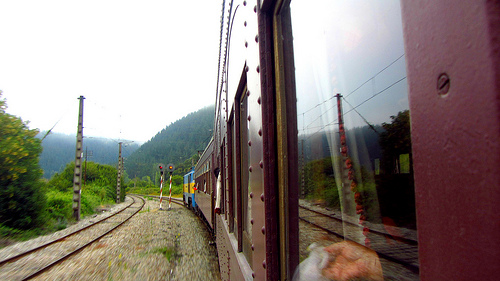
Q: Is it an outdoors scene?
A: Yes, it is outdoors.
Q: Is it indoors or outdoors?
A: It is outdoors.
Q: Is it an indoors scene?
A: No, it is outdoors.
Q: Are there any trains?
A: Yes, there is a train.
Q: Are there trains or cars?
A: Yes, there is a train.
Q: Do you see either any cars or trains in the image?
A: Yes, there is a train.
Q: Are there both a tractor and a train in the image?
A: No, there is a train but no tractors.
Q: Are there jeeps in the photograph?
A: No, there are no jeeps.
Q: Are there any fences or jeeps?
A: No, there are no jeeps or fences.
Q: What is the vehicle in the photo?
A: The vehicle is a train.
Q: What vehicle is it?
A: The vehicle is a train.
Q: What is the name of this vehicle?
A: This is a train.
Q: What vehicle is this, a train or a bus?
A: This is a train.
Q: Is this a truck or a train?
A: This is a train.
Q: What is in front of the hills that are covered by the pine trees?
A: The train is in front of the hills.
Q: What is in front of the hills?
A: The train is in front of the hills.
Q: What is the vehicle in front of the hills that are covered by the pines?
A: The vehicle is a train.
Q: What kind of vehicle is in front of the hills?
A: The vehicle is a train.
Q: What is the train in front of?
A: The train is in front of the hills.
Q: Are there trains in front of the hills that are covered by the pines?
A: Yes, there is a train in front of the hills.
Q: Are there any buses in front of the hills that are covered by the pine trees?
A: No, there is a train in front of the hills.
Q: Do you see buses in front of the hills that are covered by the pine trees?
A: No, there is a train in front of the hills.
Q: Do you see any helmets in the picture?
A: No, there are no helmets.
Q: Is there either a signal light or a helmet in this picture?
A: No, there are no helmets or traffic lights.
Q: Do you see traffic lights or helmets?
A: No, there are no helmets or traffic lights.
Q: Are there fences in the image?
A: No, there are no fences.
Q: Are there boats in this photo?
A: No, there are no boats.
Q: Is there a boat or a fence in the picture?
A: No, there are no boats or fences.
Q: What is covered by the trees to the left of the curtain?
A: The hills are covered by the pine trees.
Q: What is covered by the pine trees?
A: The hills are covered by the pine trees.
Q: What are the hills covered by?
A: The hills are covered by the pines.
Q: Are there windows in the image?
A: Yes, there is a window.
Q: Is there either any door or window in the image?
A: Yes, there is a window.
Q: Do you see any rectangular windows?
A: Yes, there is a rectangular window.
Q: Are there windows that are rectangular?
A: Yes, there is a window that is rectangular.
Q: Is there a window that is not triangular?
A: Yes, there is a rectangular window.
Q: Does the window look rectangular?
A: Yes, the window is rectangular.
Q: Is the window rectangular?
A: Yes, the window is rectangular.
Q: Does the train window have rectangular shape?
A: Yes, the window is rectangular.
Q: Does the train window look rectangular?
A: Yes, the window is rectangular.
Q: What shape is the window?
A: The window is rectangular.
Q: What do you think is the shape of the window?
A: The window is rectangular.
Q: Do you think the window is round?
A: No, the window is rectangular.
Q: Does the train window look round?
A: No, the window is rectangular.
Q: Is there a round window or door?
A: No, there is a window but it is rectangular.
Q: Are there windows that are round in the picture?
A: No, there is a window but it is rectangular.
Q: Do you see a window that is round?
A: No, there is a window but it is rectangular.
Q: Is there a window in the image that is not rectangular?
A: No, there is a window but it is rectangular.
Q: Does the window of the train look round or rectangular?
A: The window is rectangular.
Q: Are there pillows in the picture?
A: No, there are no pillows.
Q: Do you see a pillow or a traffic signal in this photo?
A: No, there are no pillows or traffic lights.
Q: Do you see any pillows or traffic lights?
A: No, there are no pillows or traffic lights.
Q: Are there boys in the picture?
A: No, there are no boys.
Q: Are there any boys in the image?
A: No, there are no boys.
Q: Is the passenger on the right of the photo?
A: Yes, the passenger is on the right of the image.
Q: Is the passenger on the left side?
A: No, the passenger is on the right of the image.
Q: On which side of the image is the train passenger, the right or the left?
A: The passenger is on the right of the image.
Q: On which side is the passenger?
A: The passenger is on the right of the image.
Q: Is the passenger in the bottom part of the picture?
A: Yes, the passenger is in the bottom of the image.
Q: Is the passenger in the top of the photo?
A: No, the passenger is in the bottom of the image.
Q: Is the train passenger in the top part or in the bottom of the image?
A: The passenger is in the bottom of the image.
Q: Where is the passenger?
A: The passenger is on the train.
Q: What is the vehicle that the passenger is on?
A: The vehicle is a train.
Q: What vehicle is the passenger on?
A: The passenger is on the train.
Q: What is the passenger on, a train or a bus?
A: The passenger is on a train.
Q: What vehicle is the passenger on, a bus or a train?
A: The passenger is on a train.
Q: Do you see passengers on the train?
A: Yes, there is a passenger on the train.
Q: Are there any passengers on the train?
A: Yes, there is a passenger on the train.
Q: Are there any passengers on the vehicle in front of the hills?
A: Yes, there is a passenger on the train.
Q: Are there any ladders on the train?
A: No, there is a passenger on the train.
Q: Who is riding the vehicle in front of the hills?
A: The passenger is riding the train.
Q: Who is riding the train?
A: The passenger is riding the train.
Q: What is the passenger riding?
A: The passenger is riding the train.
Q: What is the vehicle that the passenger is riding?
A: The vehicle is a train.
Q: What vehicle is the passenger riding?
A: The passenger is riding the train.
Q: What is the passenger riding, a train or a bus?
A: The passenger is riding a train.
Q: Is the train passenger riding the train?
A: Yes, the passenger is riding the train.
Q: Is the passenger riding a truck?
A: No, the passenger is riding the train.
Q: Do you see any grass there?
A: Yes, there is grass.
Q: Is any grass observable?
A: Yes, there is grass.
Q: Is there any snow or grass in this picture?
A: Yes, there is grass.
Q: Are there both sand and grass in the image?
A: No, there is grass but no sand.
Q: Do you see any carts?
A: No, there are no carts.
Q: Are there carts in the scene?
A: No, there are no carts.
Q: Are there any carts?
A: No, there are no carts.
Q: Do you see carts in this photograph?
A: No, there are no carts.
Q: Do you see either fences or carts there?
A: No, there are no carts or fences.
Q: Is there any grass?
A: Yes, there is grass.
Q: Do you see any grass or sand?
A: Yes, there is grass.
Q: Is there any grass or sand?
A: Yes, there is grass.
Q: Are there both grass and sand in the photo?
A: No, there is grass but no sand.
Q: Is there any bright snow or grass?
A: Yes, there is bright grass.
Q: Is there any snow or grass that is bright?
A: Yes, the grass is bright.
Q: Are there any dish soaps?
A: No, there are no dish soaps.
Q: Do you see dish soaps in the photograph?
A: No, there are no dish soaps.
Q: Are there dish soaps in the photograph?
A: No, there are no dish soaps.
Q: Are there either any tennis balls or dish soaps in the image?
A: No, there are no dish soaps or tennis balls.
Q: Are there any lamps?
A: No, there are no lamps.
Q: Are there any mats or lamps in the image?
A: No, there are no lamps or mats.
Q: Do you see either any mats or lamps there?
A: No, there are no lamps or mats.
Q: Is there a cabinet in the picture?
A: No, there are no cabinets.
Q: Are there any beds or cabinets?
A: No, there are no cabinets or beds.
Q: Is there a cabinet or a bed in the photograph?
A: No, there are no cabinets or beds.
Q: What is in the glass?
A: The curtain is in the glass.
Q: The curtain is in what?
A: The curtain is in the glass.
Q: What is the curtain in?
A: The curtain is in the glass.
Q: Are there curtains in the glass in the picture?
A: Yes, there is a curtain in the glass.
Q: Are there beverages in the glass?
A: No, there is a curtain in the glass.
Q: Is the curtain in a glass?
A: Yes, the curtain is in a glass.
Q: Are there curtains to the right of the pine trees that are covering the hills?
A: Yes, there is a curtain to the right of the pine trees.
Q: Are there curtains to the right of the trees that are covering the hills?
A: Yes, there is a curtain to the right of the pine trees.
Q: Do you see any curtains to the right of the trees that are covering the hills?
A: Yes, there is a curtain to the right of the pine trees.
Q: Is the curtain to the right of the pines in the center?
A: Yes, the curtain is to the right of the pines.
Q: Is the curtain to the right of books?
A: No, the curtain is to the right of the pines.